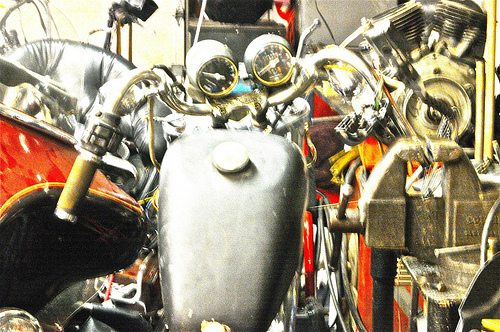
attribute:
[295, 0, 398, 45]
wall — white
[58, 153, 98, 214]
handle — yellow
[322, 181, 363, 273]
handle — clamping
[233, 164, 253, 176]
shadow — cast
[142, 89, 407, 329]
seat — large, black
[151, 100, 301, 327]
fuel tank — metallic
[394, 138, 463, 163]
teeth — metal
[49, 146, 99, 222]
handlebar — pair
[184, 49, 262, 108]
gauge — small, round